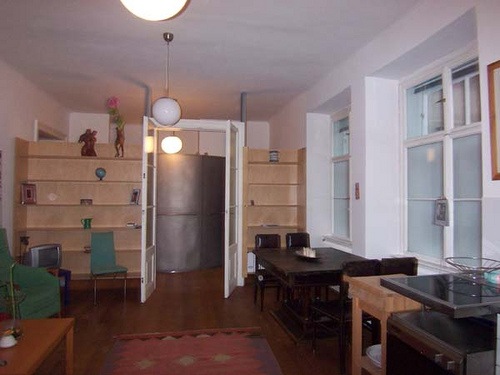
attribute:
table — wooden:
[252, 246, 371, 326]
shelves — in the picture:
[16, 137, 143, 271]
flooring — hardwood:
[181, 282, 211, 316]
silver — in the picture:
[164, 144, 215, 286]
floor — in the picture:
[24, 257, 412, 374]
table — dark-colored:
[251, 230, 370, 335]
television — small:
[18, 242, 63, 270]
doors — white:
[137, 112, 243, 304]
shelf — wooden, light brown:
[244, 200, 306, 215]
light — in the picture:
[134, 90, 194, 137]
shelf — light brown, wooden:
[14, 136, 140, 281]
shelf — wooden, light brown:
[243, 144, 306, 276]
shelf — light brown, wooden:
[11, 170, 149, 193]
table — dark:
[252, 247, 369, 342]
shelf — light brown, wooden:
[61, 250, 140, 257]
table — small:
[329, 259, 406, 364]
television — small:
[23, 231, 75, 271]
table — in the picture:
[247, 233, 401, 333]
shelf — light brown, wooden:
[17, 150, 143, 163]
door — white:
[391, 133, 495, 278]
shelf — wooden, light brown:
[245, 164, 310, 198]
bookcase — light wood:
[16, 135, 142, 290]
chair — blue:
[83, 225, 131, 302]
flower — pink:
[102, 91, 126, 125]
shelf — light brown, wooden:
[246, 178, 308, 188]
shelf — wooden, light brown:
[11, 140, 139, 273]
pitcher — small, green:
[79, 216, 96, 230]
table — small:
[51, 269, 72, 306]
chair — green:
[87, 229, 129, 306]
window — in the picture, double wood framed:
[400, 57, 490, 272]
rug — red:
[88, 325, 290, 373]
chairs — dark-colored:
[252, 225, 315, 257]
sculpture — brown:
[77, 119, 104, 171]